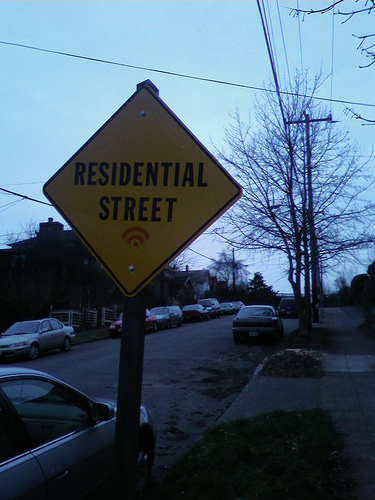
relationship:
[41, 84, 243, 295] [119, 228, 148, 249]
sign has lines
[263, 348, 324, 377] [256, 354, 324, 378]
leaves are on grass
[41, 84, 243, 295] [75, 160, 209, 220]
sign has words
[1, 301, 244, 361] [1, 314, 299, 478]
cars are on street